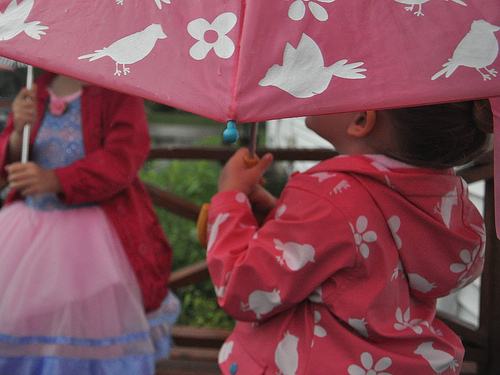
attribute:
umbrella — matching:
[0, 2, 498, 143]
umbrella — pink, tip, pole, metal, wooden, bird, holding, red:
[9, 10, 494, 139]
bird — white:
[112, 11, 171, 61]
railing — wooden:
[167, 138, 225, 178]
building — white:
[289, 131, 308, 145]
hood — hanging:
[377, 168, 479, 304]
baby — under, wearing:
[8, 87, 171, 303]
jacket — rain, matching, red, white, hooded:
[278, 189, 431, 324]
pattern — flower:
[183, 13, 248, 83]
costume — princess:
[12, 184, 194, 357]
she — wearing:
[26, 97, 174, 372]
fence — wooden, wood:
[190, 135, 223, 207]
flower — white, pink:
[209, 24, 247, 54]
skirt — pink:
[19, 218, 118, 293]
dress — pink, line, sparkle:
[16, 239, 165, 347]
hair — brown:
[396, 113, 457, 156]